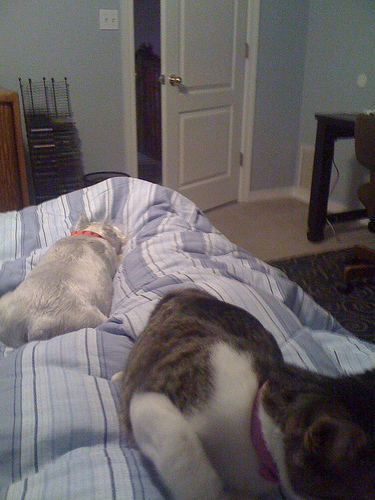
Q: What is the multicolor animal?
A: Cat.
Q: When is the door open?
A: Now.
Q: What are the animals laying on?
A: Bed.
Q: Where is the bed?
A: Bedroom.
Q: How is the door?
A: Open.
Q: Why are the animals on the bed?
A: Sleep.